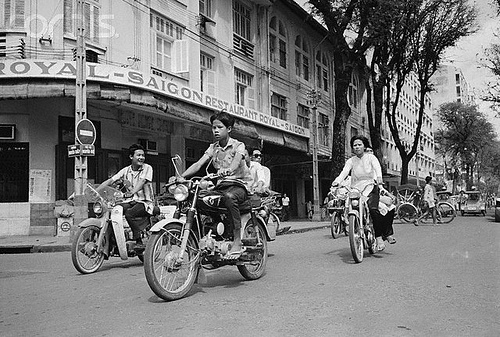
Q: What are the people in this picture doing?
A: Riding motor bikes.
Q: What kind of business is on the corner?
A: A restaurant.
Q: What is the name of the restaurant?
A: The Royal-Saigon.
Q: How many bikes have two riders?
A: Two.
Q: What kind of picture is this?
A: Black and white.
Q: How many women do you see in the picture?
A: Two.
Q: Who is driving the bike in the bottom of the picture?
A: A young boy.